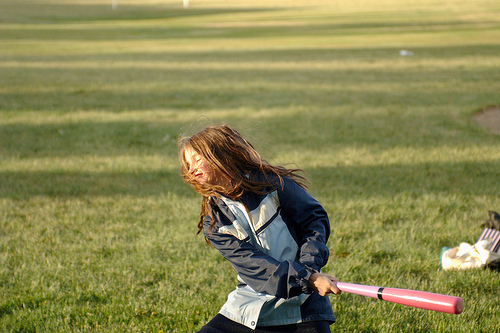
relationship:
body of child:
[192, 169, 338, 325] [178, 116, 341, 333]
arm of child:
[268, 172, 330, 268] [178, 116, 341, 333]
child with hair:
[178, 116, 341, 333] [180, 122, 303, 232]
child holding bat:
[178, 116, 341, 333] [326, 280, 460, 314]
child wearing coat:
[178, 116, 341, 333] [201, 168, 336, 330]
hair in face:
[180, 122, 303, 232] [182, 146, 218, 183]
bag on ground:
[470, 223, 484, 255] [6, 4, 484, 327]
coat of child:
[190, 168, 342, 325] [178, 116, 341, 333]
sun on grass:
[26, 198, 55, 221] [10, 176, 142, 321]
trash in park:
[392, 40, 418, 64] [85, 23, 465, 119]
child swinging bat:
[178, 116, 341, 333] [327, 274, 468, 319]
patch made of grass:
[18, 262, 86, 327] [13, 279, 108, 331]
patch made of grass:
[91, 280, 158, 330] [16, 233, 172, 324]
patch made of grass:
[130, 280, 176, 318] [83, 266, 179, 331]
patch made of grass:
[71, 167, 115, 220] [30, 120, 147, 291]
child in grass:
[178, 116, 338, 331] [72, 144, 170, 325]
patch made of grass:
[16, 23, 56, 65] [20, 32, 103, 129]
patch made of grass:
[103, 41, 163, 81] [48, 26, 153, 105]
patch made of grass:
[156, 22, 242, 70] [72, 30, 337, 106]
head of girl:
[182, 134, 256, 210] [192, 129, 336, 333]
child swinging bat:
[178, 116, 341, 333] [301, 267, 475, 333]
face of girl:
[172, 138, 210, 188] [242, 246, 296, 295]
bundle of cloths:
[442, 236, 486, 286] [458, 245, 472, 272]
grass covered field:
[15, 77, 485, 333] [64, 128, 354, 259]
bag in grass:
[470, 211, 499, 254] [445, 197, 497, 333]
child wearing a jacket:
[178, 116, 341, 333] [216, 224, 318, 291]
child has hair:
[178, 116, 341, 333] [205, 139, 287, 195]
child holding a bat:
[178, 116, 341, 333] [299, 285, 468, 333]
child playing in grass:
[178, 116, 341, 333] [101, 266, 498, 333]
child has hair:
[178, 116, 341, 333] [220, 136, 300, 181]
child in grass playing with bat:
[178, 116, 341, 333] [308, 277, 468, 320]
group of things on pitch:
[443, 225, 498, 298] [432, 195, 496, 333]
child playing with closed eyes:
[178, 116, 341, 333] [182, 153, 207, 188]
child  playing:
[178, 116, 341, 333] [268, 287, 443, 333]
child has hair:
[178, 116, 341, 333] [180, 122, 303, 232]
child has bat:
[178, 116, 341, 333] [329, 274, 462, 316]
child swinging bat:
[178, 116, 341, 333] [329, 274, 462, 316]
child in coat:
[178, 116, 341, 333] [201, 168, 336, 330]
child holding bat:
[178, 116, 341, 333] [329, 274, 462, 316]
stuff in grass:
[434, 209, 498, 278] [325, 151, 496, 326]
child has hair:
[178, 116, 341, 333] [175, 124, 303, 221]